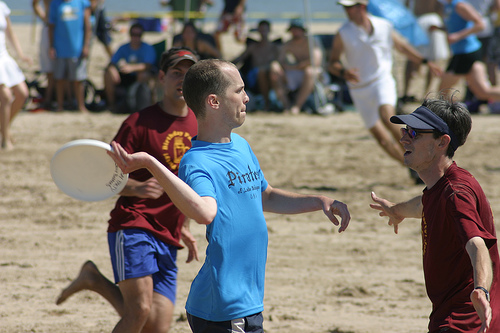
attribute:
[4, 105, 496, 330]
sand — light brown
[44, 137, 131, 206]
frisbee — white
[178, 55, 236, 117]
hair — dark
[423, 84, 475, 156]
hair — short, man's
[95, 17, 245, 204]
man — standing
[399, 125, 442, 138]
sunglasses — A pair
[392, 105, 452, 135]
sunvisor — dark blue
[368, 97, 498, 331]
man — adult, grown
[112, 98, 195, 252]
shirt — red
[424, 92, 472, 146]
hair — man's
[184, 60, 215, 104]
hair — brown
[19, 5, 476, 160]
spectators — watching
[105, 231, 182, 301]
shorts — blue, sports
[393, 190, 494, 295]
arms — outwards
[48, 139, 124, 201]
frisbee — white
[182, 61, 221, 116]
man's hair — short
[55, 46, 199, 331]
person — running barefooted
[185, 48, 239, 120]
hair — man's, brown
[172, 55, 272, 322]
man — grown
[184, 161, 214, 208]
sleeve — short